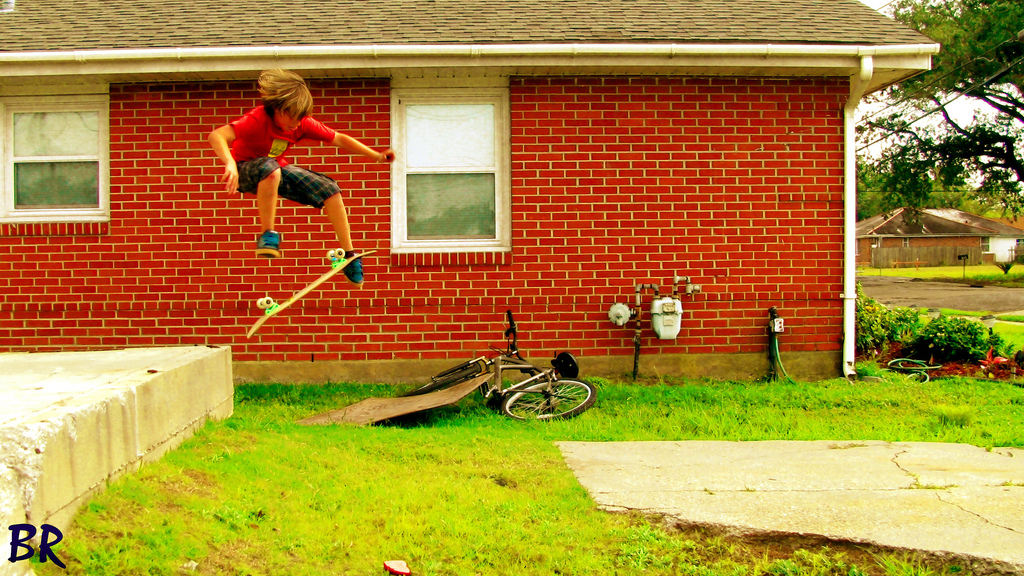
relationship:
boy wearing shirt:
[208, 67, 395, 287] [224, 105, 336, 167]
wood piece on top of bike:
[317, 369, 492, 426] [412, 307, 597, 425]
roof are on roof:
[0, 0, 937, 51] [1, 2, 948, 73]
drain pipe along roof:
[5, 32, 942, 68] [5, 0, 942, 68]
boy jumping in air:
[208, 67, 395, 287] [155, 165, 577, 503]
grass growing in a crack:
[883, 476, 956, 495] [883, 476, 956, 495]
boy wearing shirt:
[192, 47, 382, 269] [182, 112, 345, 179]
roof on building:
[0, 0, 937, 51] [0, 0, 941, 386]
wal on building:
[4, 41, 846, 367] [6, 11, 922, 388]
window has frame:
[397, 90, 492, 247] [378, 48, 538, 288]